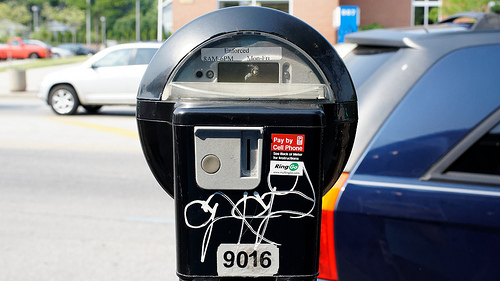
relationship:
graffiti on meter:
[180, 160, 318, 262] [134, 5, 359, 280]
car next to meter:
[318, 26, 500, 279] [134, 5, 359, 280]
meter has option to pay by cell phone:
[134, 5, 359, 280] [269, 131, 305, 153]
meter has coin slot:
[134, 5, 359, 280] [245, 135, 253, 172]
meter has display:
[134, 5, 359, 280] [214, 59, 282, 87]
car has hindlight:
[318, 26, 500, 279] [317, 171, 353, 280]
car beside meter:
[318, 26, 500, 279] [134, 5, 359, 280]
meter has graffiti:
[134, 5, 359, 280] [180, 160, 318, 262]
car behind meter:
[26, 40, 165, 117] [134, 5, 359, 280]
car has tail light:
[318, 26, 500, 279] [318, 171, 353, 280]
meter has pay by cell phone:
[134, 5, 359, 280] [269, 134, 305, 152]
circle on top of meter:
[134, 5, 359, 198] [134, 5, 359, 280]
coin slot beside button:
[245, 135, 253, 172] [199, 153, 222, 174]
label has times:
[200, 44, 283, 64] [202, 53, 235, 64]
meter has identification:
[134, 5, 359, 280] [214, 240, 282, 278]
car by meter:
[318, 26, 500, 279] [134, 5, 359, 280]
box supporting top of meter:
[171, 107, 328, 280] [137, 4, 360, 198]